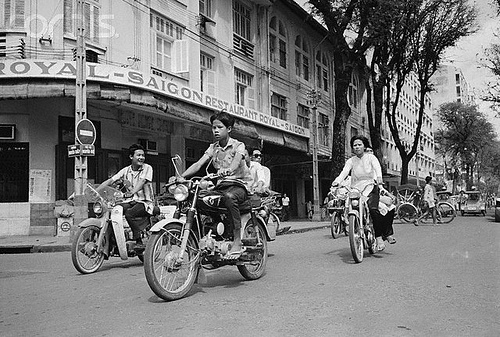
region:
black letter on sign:
[9, 60, 29, 76]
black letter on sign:
[35, 57, 56, 77]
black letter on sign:
[58, 62, 76, 77]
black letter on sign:
[88, 62, 109, 78]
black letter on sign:
[128, 70, 144, 87]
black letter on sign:
[144, 75, 159, 90]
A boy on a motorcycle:
[146, 108, 278, 298]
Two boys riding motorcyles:
[71, 110, 268, 297]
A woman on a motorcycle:
[335, 135, 385, 262]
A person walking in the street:
[419, 173, 439, 228]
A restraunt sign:
[0, 59, 312, 140]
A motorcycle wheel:
[146, 223, 199, 301]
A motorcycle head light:
[173, 183, 187, 202]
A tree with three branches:
[383, 0, 431, 184]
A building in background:
[420, 61, 475, 191]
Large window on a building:
[131, 10, 186, 72]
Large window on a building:
[195, 49, 227, 99]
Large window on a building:
[231, 69, 257, 119]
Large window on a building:
[268, 82, 295, 120]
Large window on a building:
[290, 100, 309, 137]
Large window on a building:
[312, 107, 336, 162]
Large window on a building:
[312, 37, 335, 92]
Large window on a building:
[265, 15, 290, 73]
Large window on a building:
[231, 0, 256, 59]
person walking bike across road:
[394, 173, 460, 228]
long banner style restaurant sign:
[1, 56, 313, 141]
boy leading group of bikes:
[140, 110, 282, 305]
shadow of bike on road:
[146, 258, 249, 309]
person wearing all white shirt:
[324, 133, 402, 262]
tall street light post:
[64, 1, 100, 246]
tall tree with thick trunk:
[306, 1, 417, 230]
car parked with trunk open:
[456, 185, 490, 217]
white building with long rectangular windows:
[424, 63, 473, 125]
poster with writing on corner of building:
[26, 163, 55, 206]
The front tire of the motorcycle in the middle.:
[140, 225, 197, 291]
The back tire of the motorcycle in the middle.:
[235, 215, 269, 277]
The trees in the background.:
[316, 2, 498, 204]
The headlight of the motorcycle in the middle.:
[169, 183, 189, 198]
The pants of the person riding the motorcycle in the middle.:
[205, 179, 246, 246]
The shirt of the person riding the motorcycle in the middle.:
[199, 146, 250, 181]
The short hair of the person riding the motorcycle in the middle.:
[207, 115, 232, 125]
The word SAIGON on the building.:
[122, 69, 207, 107]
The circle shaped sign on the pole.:
[76, 120, 96, 140]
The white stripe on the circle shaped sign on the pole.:
[76, 123, 97, 137]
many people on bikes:
[103, 111, 424, 287]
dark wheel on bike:
[146, 227, 203, 317]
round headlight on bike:
[163, 167, 193, 230]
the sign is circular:
[75, 117, 96, 145]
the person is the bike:
[145, 109, 266, 299]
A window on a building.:
[148, 30, 177, 71]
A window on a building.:
[200, 53, 225, 92]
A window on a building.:
[235, 67, 257, 109]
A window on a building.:
[271, 95, 286, 110]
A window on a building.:
[270, 27, 282, 69]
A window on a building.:
[298, 41, 305, 73]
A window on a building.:
[318, 52, 327, 92]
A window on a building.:
[316, 106, 330, 139]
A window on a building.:
[298, 104, 310, 128]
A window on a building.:
[376, 142, 394, 172]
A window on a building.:
[141, 23, 178, 75]